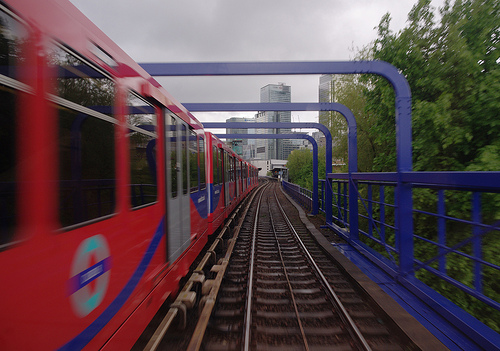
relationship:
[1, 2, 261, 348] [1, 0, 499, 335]
train on train tracks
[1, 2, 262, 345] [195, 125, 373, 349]
train on tracks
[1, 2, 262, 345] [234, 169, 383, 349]
train on tracks